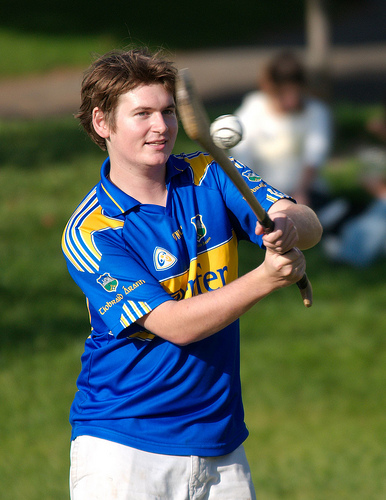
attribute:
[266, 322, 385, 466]
grass — lush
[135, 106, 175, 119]
eyes — open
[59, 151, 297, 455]
jersey — yellow and blue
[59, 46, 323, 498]
he — playing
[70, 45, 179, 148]
hair — brown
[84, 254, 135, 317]
emblem — school emblem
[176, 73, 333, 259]
stick — brown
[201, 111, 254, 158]
ball — white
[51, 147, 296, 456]
shirt — short-sleeved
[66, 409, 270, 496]
pants — white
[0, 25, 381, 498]
grass — green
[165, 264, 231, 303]
lettering — yellow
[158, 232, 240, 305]
background — yellow